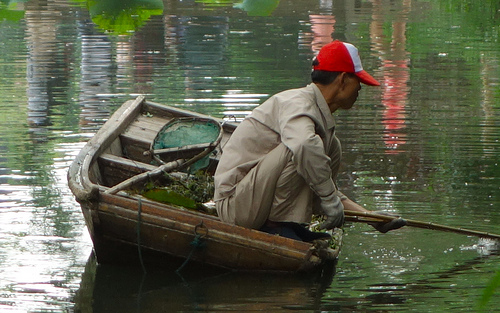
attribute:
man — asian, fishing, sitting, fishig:
[214, 40, 406, 242]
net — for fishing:
[349, 207, 500, 251]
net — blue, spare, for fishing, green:
[152, 117, 223, 177]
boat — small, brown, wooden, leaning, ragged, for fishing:
[66, 99, 346, 274]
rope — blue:
[135, 198, 200, 274]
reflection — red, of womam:
[370, 0, 414, 156]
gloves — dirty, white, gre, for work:
[317, 191, 407, 232]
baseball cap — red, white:
[311, 38, 383, 89]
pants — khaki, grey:
[214, 132, 341, 229]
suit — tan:
[213, 88, 352, 233]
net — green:
[150, 187, 197, 210]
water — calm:
[0, 1, 499, 313]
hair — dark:
[311, 57, 355, 86]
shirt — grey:
[211, 87, 341, 206]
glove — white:
[318, 196, 346, 237]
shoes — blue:
[264, 220, 331, 243]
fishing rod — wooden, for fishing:
[346, 209, 499, 243]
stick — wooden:
[147, 143, 215, 157]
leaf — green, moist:
[83, 2, 165, 36]